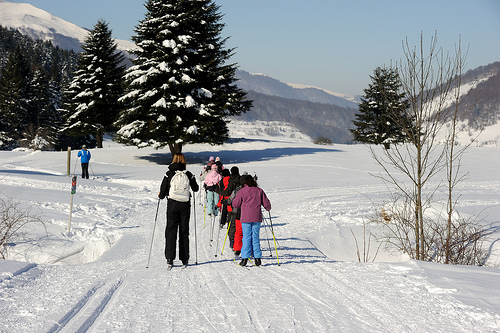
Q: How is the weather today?
A: It is overcast.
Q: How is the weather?
A: It is overcast.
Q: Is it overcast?
A: Yes, it is overcast.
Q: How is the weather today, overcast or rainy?
A: It is overcast.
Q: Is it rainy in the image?
A: No, it is overcast.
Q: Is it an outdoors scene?
A: Yes, it is outdoors.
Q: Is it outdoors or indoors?
A: It is outdoors.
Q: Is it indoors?
A: No, it is outdoors.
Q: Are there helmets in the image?
A: No, there are no helmets.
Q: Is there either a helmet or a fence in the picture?
A: No, there are no helmets or fences.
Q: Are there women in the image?
A: Yes, there is a woman.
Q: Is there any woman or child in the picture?
A: Yes, there is a woman.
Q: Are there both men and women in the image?
A: Yes, there are both a woman and a man.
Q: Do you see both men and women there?
A: Yes, there are both a woman and a man.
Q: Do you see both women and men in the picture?
A: Yes, there are both a woman and a man.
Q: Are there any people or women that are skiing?
A: Yes, the woman is skiing.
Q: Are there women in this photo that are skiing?
A: Yes, there is a woman that is skiing.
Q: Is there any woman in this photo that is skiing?
A: Yes, there is a woman that is skiing.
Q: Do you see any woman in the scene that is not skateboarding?
A: Yes, there is a woman that is skiing .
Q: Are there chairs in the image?
A: No, there are no chairs.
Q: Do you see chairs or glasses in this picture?
A: No, there are no chairs or glasses.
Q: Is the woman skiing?
A: Yes, the woman is skiing.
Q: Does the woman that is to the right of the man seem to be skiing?
A: Yes, the woman is skiing.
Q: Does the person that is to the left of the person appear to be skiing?
A: Yes, the woman is skiing.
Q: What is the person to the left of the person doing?
A: The woman is skiing.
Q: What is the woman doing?
A: The woman is skiing.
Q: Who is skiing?
A: The woman is skiing.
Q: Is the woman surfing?
A: No, the woman is skiing.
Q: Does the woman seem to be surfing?
A: No, the woman is skiing.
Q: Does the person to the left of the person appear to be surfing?
A: No, the woman is skiing.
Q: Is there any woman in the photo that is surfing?
A: No, there is a woman but she is skiing.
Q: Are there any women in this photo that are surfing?
A: No, there is a woman but she is skiing.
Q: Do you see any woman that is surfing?
A: No, there is a woman but she is skiing.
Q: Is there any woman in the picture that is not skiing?
A: No, there is a woman but she is skiing.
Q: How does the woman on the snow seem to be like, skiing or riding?
A: The woman is skiing.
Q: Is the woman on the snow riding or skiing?
A: The woman is skiing.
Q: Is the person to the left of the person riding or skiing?
A: The woman is skiing.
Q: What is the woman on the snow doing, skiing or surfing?
A: The woman is skiing.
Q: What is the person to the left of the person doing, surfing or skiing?
A: The woman is skiing.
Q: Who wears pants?
A: The woman wears pants.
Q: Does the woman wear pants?
A: Yes, the woman wears pants.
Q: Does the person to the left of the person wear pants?
A: Yes, the woman wears pants.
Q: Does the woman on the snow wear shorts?
A: No, the woman wears pants.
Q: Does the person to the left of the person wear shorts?
A: No, the woman wears pants.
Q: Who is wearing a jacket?
A: The woman is wearing a jacket.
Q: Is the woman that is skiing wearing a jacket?
A: Yes, the woman is wearing a jacket.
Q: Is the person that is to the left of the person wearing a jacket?
A: Yes, the woman is wearing a jacket.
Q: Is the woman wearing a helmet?
A: No, the woman is wearing a jacket.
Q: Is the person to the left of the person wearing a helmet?
A: No, the woman is wearing a jacket.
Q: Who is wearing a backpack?
A: The woman is wearing a backpack.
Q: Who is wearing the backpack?
A: The woman is wearing a backpack.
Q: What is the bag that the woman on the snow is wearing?
A: The bag is a backpack.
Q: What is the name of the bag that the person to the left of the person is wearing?
A: The bag is a backpack.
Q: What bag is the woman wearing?
A: The woman is wearing a backpack.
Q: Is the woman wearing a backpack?
A: Yes, the woman is wearing a backpack.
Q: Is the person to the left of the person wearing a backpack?
A: Yes, the woman is wearing a backpack.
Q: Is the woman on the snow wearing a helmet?
A: No, the woman is wearing a backpack.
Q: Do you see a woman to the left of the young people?
A: Yes, there is a woman to the left of the people.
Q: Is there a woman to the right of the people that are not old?
A: No, the woman is to the left of the people.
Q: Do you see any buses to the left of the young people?
A: No, there is a woman to the left of the people.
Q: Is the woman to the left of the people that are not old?
A: Yes, the woman is to the left of the people.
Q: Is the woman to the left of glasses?
A: No, the woman is to the left of the people.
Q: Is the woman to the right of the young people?
A: No, the woman is to the left of the people.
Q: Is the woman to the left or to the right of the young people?
A: The woman is to the left of the people.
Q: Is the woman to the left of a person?
A: Yes, the woman is to the left of a person.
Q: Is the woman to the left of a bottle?
A: No, the woman is to the left of a person.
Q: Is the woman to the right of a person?
A: No, the woman is to the left of a person.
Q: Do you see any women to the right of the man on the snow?
A: Yes, there is a woman to the right of the man.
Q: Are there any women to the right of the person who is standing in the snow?
A: Yes, there is a woman to the right of the man.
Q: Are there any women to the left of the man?
A: No, the woman is to the right of the man.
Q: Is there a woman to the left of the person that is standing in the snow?
A: No, the woman is to the right of the man.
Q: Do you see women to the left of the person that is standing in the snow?
A: No, the woman is to the right of the man.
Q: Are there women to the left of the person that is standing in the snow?
A: No, the woman is to the right of the man.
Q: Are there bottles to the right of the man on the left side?
A: No, there is a woman to the right of the man.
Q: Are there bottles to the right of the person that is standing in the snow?
A: No, there is a woman to the right of the man.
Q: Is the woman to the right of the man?
A: Yes, the woman is to the right of the man.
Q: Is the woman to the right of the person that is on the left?
A: Yes, the woman is to the right of the man.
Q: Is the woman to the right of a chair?
A: No, the woman is to the right of the man.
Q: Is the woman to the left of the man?
A: No, the woman is to the right of the man.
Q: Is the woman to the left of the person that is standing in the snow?
A: No, the woman is to the right of the man.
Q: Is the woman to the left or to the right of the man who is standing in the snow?
A: The woman is to the right of the man.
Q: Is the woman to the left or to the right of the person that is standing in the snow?
A: The woman is to the right of the man.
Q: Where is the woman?
A: The woman is on the snow.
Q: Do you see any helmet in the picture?
A: No, there are no helmets.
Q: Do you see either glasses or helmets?
A: No, there are no helmets or glasses.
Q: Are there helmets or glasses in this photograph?
A: No, there are no helmets or glasses.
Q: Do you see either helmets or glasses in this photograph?
A: No, there are no helmets or glasses.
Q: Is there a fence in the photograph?
A: No, there are no fences.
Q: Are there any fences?
A: No, there are no fences.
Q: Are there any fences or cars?
A: No, there are no fences or cars.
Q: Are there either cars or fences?
A: No, there are no fences or cars.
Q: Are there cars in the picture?
A: No, there are no cars.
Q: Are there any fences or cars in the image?
A: No, there are no cars or fences.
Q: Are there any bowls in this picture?
A: No, there are no bowls.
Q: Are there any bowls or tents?
A: No, there are no bowls or tents.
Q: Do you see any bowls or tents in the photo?
A: No, there are no bowls or tents.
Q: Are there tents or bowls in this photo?
A: No, there are no bowls or tents.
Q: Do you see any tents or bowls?
A: No, there are no bowls or tents.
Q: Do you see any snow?
A: Yes, there is snow.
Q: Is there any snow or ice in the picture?
A: Yes, there is snow.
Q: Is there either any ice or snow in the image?
A: Yes, there is snow.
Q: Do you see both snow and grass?
A: No, there is snow but no grass.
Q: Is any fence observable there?
A: No, there are no fences.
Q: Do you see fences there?
A: No, there are no fences.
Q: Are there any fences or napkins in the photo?
A: No, there are no fences or napkins.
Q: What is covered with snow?
A: The mountain is covered with snow.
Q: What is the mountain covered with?
A: The mountain is covered with snow.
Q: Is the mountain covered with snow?
A: Yes, the mountain is covered with snow.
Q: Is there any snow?
A: Yes, there is snow.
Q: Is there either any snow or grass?
A: Yes, there is snow.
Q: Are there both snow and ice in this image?
A: No, there is snow but no ice.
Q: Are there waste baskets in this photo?
A: No, there are no waste baskets.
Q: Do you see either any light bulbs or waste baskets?
A: No, there are no waste baskets or light bulbs.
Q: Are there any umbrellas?
A: No, there are no umbrellas.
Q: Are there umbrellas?
A: No, there are no umbrellas.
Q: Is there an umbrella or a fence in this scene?
A: No, there are no umbrellas or fences.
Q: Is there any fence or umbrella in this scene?
A: No, there are no umbrellas or fences.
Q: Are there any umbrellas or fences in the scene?
A: No, there are no umbrellas or fences.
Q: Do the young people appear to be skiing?
A: Yes, the people are skiing.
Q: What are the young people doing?
A: The people are skiing.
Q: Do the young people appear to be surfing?
A: No, the people are skiing.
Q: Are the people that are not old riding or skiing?
A: The people are skiing.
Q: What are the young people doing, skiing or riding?
A: The people are skiing.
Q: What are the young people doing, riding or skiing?
A: The people are skiing.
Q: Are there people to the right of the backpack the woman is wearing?
A: Yes, there are people to the right of the backpack.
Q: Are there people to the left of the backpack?
A: No, the people are to the right of the backpack.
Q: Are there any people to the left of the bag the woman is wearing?
A: No, the people are to the right of the backpack.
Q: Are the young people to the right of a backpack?
A: Yes, the people are to the right of a backpack.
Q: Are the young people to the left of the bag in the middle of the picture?
A: No, the people are to the right of the backpack.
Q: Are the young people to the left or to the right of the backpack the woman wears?
A: The people are to the right of the backpack.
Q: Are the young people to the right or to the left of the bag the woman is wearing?
A: The people are to the right of the backpack.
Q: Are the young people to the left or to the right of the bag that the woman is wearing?
A: The people are to the right of the backpack.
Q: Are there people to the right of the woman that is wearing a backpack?
A: Yes, there are people to the right of the woman.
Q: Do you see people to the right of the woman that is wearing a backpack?
A: Yes, there are people to the right of the woman.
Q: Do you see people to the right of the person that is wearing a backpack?
A: Yes, there are people to the right of the woman.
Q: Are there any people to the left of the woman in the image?
A: No, the people are to the right of the woman.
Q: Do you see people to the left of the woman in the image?
A: No, the people are to the right of the woman.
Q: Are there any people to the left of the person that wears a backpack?
A: No, the people are to the right of the woman.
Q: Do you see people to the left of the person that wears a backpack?
A: No, the people are to the right of the woman.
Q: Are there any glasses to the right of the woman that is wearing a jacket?
A: No, there are people to the right of the woman.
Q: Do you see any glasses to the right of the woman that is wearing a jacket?
A: No, there are people to the right of the woman.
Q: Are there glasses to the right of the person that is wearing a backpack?
A: No, there are people to the right of the woman.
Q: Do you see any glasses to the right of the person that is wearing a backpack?
A: No, there are people to the right of the woman.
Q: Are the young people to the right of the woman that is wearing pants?
A: Yes, the people are to the right of the woman.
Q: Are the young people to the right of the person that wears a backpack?
A: Yes, the people are to the right of the woman.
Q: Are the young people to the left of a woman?
A: No, the people are to the right of a woman.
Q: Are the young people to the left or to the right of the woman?
A: The people are to the right of the woman.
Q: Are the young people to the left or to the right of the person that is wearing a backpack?
A: The people are to the right of the woman.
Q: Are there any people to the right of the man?
A: Yes, there are people to the right of the man.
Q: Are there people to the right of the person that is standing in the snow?
A: Yes, there are people to the right of the man.